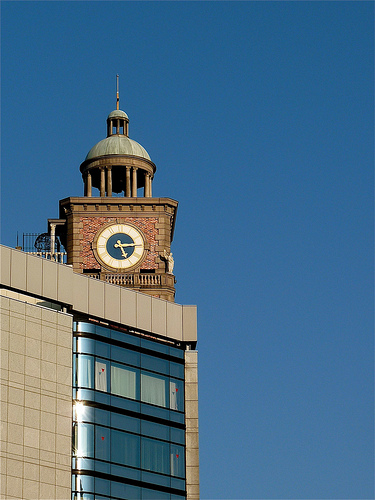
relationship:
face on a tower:
[96, 225, 146, 270] [47, 74, 177, 313]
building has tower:
[4, 71, 209, 496] [47, 74, 177, 313]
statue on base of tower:
[162, 248, 181, 281] [47, 74, 177, 313]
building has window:
[4, 71, 209, 496] [110, 362, 140, 400]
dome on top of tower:
[100, 109, 136, 121] [47, 74, 177, 313]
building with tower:
[4, 71, 209, 496] [47, 74, 177, 313]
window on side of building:
[110, 362, 140, 400] [4, 71, 209, 496]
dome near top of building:
[100, 109, 136, 121] [4, 71, 209, 496]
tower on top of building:
[47, 74, 177, 313] [4, 71, 209, 496]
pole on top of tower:
[110, 66, 127, 109] [47, 74, 177, 313]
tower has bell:
[47, 74, 177, 313] [109, 173, 130, 194]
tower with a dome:
[47, 74, 177, 313] [100, 109, 136, 121]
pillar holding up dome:
[96, 165, 109, 196] [79, 135, 168, 193]